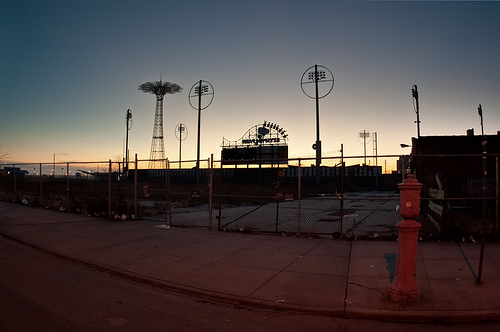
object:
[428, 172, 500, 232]
trash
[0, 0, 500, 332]
amusement park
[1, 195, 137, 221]
trash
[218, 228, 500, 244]
trash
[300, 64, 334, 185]
structure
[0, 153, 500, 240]
fencing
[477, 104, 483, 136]
pole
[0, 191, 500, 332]
cement square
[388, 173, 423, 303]
structure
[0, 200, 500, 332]
road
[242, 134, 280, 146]
sign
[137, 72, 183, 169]
tower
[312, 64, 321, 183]
pole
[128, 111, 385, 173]
sunset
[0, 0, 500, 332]
square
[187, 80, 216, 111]
circle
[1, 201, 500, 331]
curb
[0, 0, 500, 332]
street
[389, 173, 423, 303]
fire hydrant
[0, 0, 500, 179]
sky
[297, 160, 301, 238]
post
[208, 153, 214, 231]
post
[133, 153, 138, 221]
post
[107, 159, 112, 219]
post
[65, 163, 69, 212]
post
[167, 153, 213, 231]
gate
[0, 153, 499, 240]
fence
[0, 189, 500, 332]
ground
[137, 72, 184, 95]
top